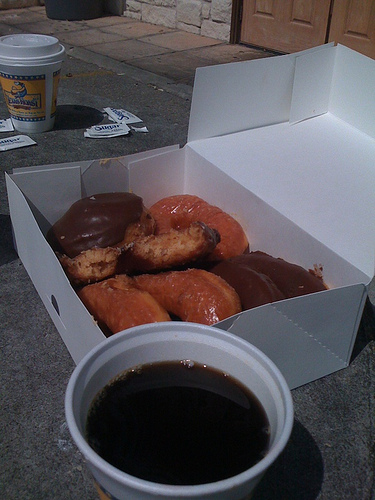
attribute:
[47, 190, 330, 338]
donuts — glazed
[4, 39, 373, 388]
box — white, cardboard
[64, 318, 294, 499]
cup — white, plastic, small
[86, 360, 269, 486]
coffee — black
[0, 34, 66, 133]
cup — white, small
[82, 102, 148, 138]
packs — torn, white, blue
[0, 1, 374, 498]
floor — grey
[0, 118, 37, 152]
packs — white, blue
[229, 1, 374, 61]
doors — wooden, brown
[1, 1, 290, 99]
walk way — stone, red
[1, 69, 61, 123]
design — blue, yellow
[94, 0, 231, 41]
wall — stone